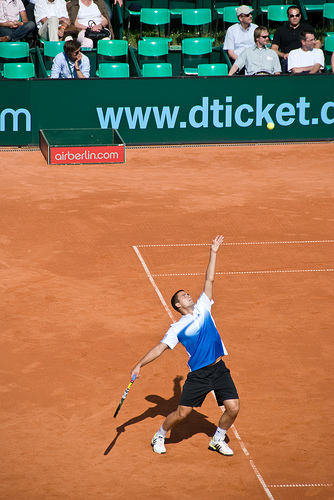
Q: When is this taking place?
A: Daytime.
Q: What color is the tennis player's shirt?
A: Blue and white.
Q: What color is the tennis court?
A: Light brown.